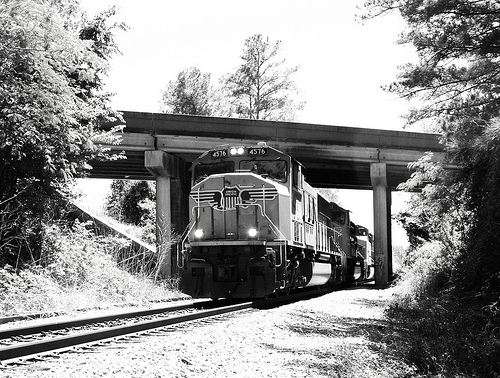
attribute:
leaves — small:
[0, 0, 130, 191]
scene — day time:
[0, 1, 497, 376]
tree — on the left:
[0, 0, 142, 297]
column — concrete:
[366, 166, 393, 283]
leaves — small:
[391, 130, 476, 250]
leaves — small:
[1, 1, 125, 209]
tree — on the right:
[361, 8, 498, 366]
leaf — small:
[407, 161, 411, 165]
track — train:
[0, 285, 340, 370]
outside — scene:
[2, 3, 498, 375]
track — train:
[4, 295, 264, 339]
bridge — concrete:
[31, 103, 460, 292]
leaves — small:
[187, 90, 197, 105]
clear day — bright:
[5, 7, 499, 360]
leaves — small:
[391, 259, 453, 326]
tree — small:
[221, 40, 299, 122]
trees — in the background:
[151, 12, 306, 134]